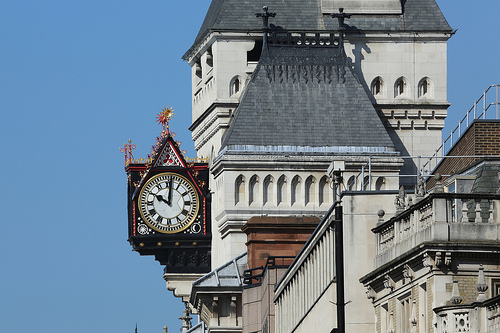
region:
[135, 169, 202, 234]
black white and gold clock on a building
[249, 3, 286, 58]
black cross on a building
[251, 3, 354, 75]
two crosses on top of a building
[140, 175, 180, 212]
two black hands on a clock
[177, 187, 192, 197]
black roman numeral two on a clock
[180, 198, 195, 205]
black roman numeral three on a clock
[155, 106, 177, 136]
yellow and red decorations hanging on top of a building clock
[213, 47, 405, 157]
gray roof of a building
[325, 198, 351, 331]
black pole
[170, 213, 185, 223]
black roman numeral five on a clock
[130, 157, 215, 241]
big analog roman clock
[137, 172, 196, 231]
the clock on the building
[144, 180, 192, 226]
the roman numerals on the clock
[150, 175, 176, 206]
the black clock hands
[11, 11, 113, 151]
the clear blue sky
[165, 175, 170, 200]
the black minute hand on the clock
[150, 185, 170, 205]
the black hour hand on the clock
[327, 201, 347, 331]
the tall black pole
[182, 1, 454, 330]
the tall building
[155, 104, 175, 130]
the gold item on the top of the clock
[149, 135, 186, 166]
the triangle on top of the clock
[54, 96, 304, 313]
an outside clock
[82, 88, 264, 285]
a clock that is outside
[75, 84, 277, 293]
clock extending from building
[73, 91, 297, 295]
clock on a building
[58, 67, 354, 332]
clock at the top of the building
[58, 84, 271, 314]
a large outside clock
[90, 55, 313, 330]
a clock with a pointed top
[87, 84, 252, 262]
a clock with a gold ring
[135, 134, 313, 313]
a clock with black numbers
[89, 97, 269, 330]
a clock with black arms